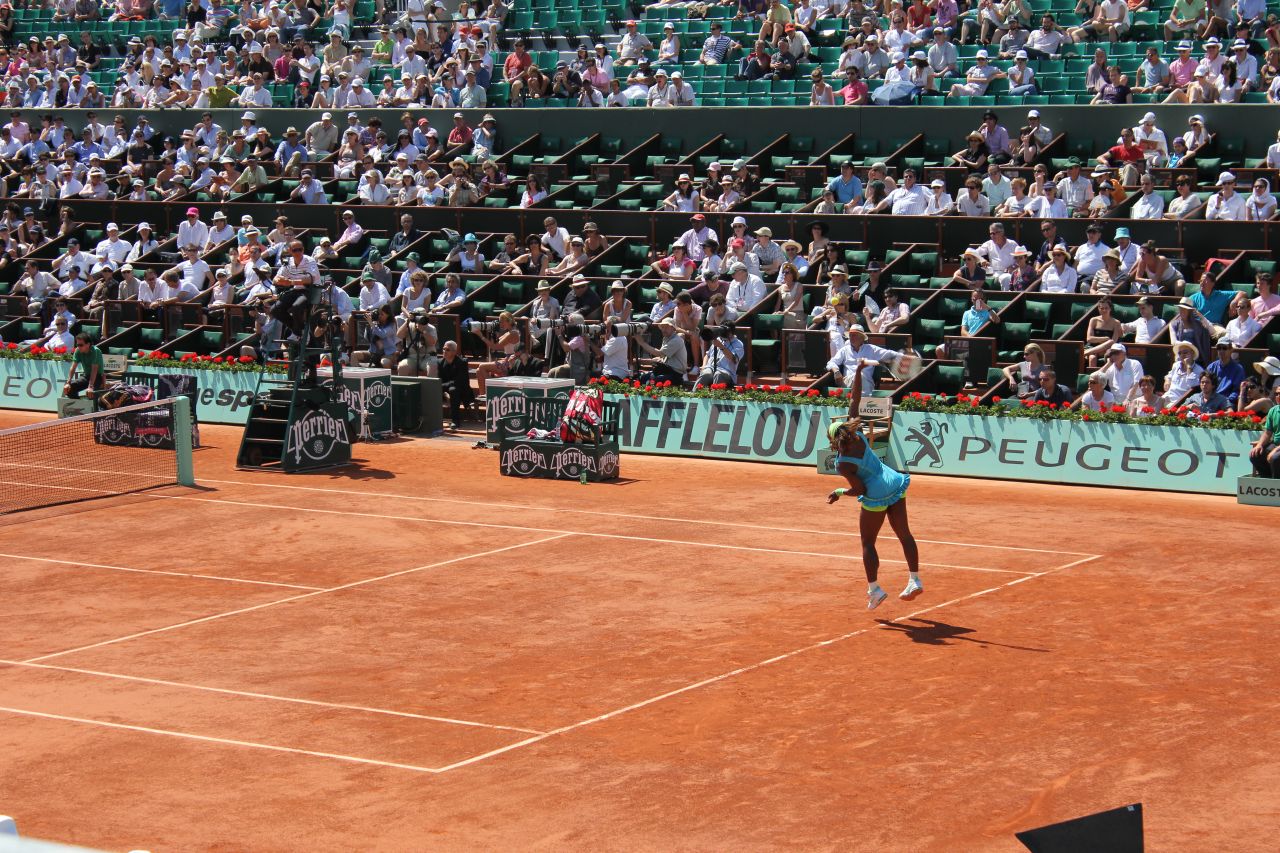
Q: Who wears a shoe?
A: The man wears a shoe.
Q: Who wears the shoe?
A: The man wears a shoe.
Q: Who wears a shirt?
A: The man wears a shirt.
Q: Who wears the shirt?
A: The man wears a shirt.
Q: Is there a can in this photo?
A: No, there are no cans.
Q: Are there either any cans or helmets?
A: No, there are no cans or helmets.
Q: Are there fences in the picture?
A: No, there are no fences.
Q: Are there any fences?
A: No, there are no fences.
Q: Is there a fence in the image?
A: No, there are no fences.